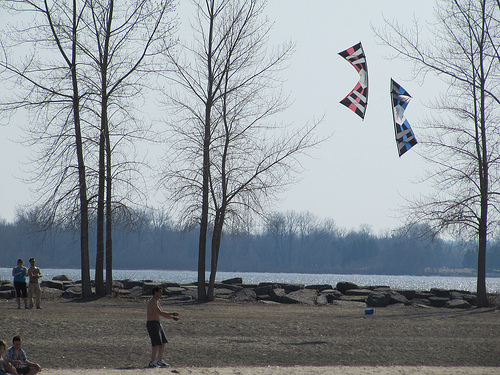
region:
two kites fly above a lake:
[6, 3, 498, 292]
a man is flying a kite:
[141, 279, 187, 372]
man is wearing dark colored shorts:
[141, 282, 181, 368]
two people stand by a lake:
[10, 255, 46, 310]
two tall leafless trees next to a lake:
[0, 0, 335, 300]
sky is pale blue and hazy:
[1, 0, 493, 245]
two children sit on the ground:
[0, 332, 42, 372]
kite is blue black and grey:
[385, 76, 418, 154]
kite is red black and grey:
[337, 40, 372, 120]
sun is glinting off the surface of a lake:
[1, 263, 499, 298]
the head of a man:
[139, 280, 183, 305]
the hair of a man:
[145, 274, 170, 306]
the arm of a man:
[149, 283, 197, 323]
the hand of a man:
[160, 295, 191, 330]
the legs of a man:
[144, 322, 187, 368]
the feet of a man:
[147, 346, 195, 370]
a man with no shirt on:
[136, 255, 200, 329]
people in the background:
[13, 174, 131, 308]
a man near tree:
[130, 166, 282, 341]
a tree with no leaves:
[169, 108, 294, 232]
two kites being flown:
[330, 33, 423, 159]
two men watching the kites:
[10, 247, 40, 304]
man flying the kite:
[135, 280, 185, 365]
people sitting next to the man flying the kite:
[0, 330, 36, 370]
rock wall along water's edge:
[0, 260, 495, 310]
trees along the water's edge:
[40, 126, 490, 286]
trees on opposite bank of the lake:
[5, 205, 485, 265]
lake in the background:
[8, 260, 490, 293]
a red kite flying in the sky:
[327, 40, 375, 133]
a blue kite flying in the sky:
[380, 72, 415, 162]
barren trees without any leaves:
[188, 27, 275, 219]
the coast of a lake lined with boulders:
[231, 272, 303, 318]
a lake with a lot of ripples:
[385, 272, 423, 292]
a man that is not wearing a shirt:
[135, 284, 184, 364]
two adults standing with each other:
[4, 259, 64, 316]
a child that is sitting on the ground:
[8, 339, 44, 374]